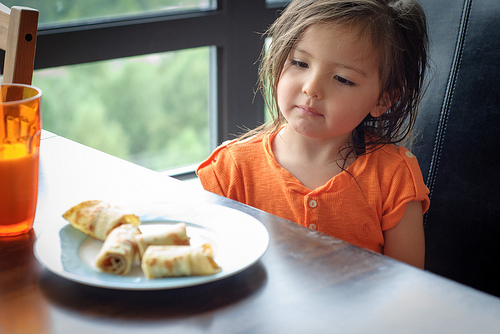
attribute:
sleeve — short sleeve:
[350, 153, 434, 211]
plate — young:
[33, 195, 270, 292]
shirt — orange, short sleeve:
[194, 122, 431, 255]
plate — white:
[28, 190, 275, 299]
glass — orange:
[1, 80, 43, 243]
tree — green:
[75, 71, 201, 164]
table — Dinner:
[0, 129, 497, 330]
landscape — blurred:
[20, 49, 210, 162]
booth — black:
[406, 2, 499, 282]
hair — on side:
[257, 1, 437, 155]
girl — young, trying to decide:
[189, 0, 438, 270]